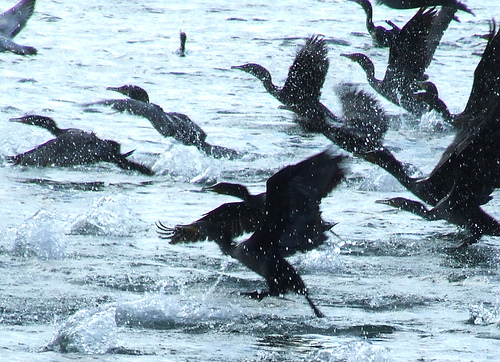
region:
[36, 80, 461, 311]
birds flying over surface of water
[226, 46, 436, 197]
one dark line formed by two birds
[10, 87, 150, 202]
water drops over bird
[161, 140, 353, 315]
two birds competing for same space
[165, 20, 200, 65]
tail feathers of submerged bird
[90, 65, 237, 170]
bird ascending into air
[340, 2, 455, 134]
wings extended above body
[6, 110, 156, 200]
wings level with body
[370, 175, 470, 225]
neck bent at right angle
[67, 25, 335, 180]
turquoise and silver hues to water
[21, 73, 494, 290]
the birds are flying close to the water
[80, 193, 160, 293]
there is water droplets in the air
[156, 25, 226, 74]
the bird is the water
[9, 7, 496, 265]
there are 10 birds in the air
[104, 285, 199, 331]
the water is blue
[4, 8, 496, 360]
the photo was taken during daytime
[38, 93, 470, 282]
the birds are flapping their wings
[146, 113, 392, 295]
the birds are black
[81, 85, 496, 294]
the birds are black together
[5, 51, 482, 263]
the birds are wet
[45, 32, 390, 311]
Birds in the water.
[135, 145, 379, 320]
Black birds in the air.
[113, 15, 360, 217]
Water under the birds.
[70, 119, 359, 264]
Splashing water below birds.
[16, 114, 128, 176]
Wings on the bird.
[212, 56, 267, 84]
Beak on the bird.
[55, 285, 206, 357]
Waves in the ocean.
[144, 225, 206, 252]
Ruffles on the wings.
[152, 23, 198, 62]
duck in the water.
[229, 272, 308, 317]
Birds feet in the water.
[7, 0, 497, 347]
grey rainy outdoor scene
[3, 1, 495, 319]
birds with wings spread flying over water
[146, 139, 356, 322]
black water bird flying with tail in water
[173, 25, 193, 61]
head of black bird in water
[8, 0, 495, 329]
flock of black sea birds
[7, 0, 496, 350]
choppy white and blue water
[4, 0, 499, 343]
black birds splashing in water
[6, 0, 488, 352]
droplets of water and rain over water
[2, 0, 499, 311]
black birds with large wings expanded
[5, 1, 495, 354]
blue water being pummled by rain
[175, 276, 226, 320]
water splashing in the air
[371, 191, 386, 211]
beak on a bird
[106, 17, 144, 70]
calm ripples in the water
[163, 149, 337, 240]
a bird landing in the water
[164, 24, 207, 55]
a duck swimming alone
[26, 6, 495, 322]
a flock of ducks playing in a river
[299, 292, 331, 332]
a tail feather fanning the water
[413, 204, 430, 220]
water droplets landing on a bird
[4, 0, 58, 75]
a duck flying away from the flock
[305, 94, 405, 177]
a duck frantically flapping it's wings